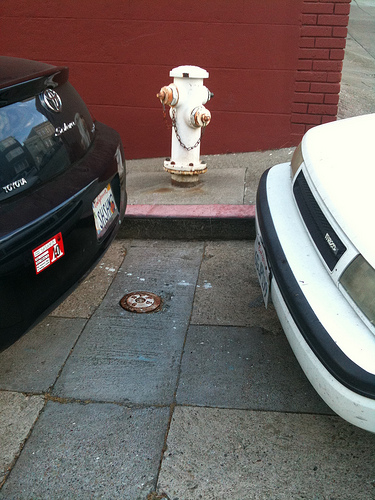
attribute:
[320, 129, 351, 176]
car — white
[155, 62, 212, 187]
hydrant — white, fire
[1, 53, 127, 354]
car — black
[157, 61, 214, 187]
fire hydrant — white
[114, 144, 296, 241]
curb — faded, red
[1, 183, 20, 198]
mark — toyota trade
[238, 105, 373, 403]
cars — illegally parked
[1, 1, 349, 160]
wall — red, brick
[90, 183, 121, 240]
plate — california, license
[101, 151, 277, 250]
curb — red, painted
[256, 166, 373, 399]
bumper — black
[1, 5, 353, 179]
building — red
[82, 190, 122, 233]
license plate — white